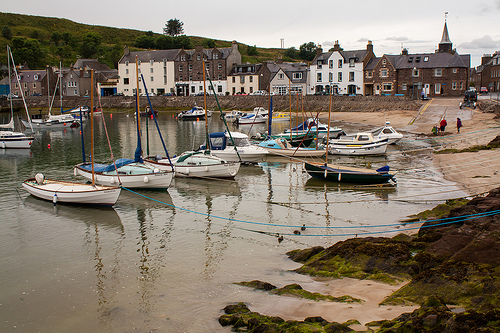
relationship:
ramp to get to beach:
[409, 94, 469, 139] [393, 150, 492, 320]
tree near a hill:
[163, 16, 186, 36] [0, 10, 187, 42]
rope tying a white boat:
[119, 183, 499, 231] [21, 173, 122, 207]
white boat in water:
[21, 173, 122, 207] [0, 101, 445, 328]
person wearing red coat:
[437, 117, 447, 134] [440, 120, 447, 125]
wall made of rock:
[93, 55, 498, 141] [90, 45, 472, 150]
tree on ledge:
[157, 15, 188, 40] [161, 17, 182, 36]